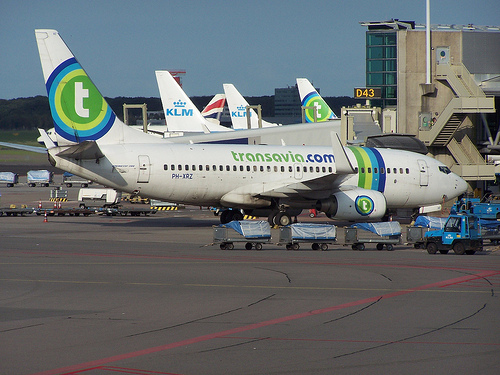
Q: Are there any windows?
A: Yes, there is a window.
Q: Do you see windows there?
A: Yes, there is a window.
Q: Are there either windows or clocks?
A: Yes, there is a window.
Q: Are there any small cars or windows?
A: Yes, there is a small window.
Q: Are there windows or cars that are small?
A: Yes, the window is small.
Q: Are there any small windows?
A: Yes, there is a small window.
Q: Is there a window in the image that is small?
A: Yes, there is a window that is small.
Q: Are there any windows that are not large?
A: Yes, there is a small window.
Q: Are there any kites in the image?
A: No, there are no kites.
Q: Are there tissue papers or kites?
A: No, there are no kites or tissue papers.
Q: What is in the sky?
A: The clouds are in the sky.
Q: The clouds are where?
A: The clouds are in the sky.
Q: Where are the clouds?
A: The clouds are in the sky.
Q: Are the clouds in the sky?
A: Yes, the clouds are in the sky.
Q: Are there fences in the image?
A: No, there are no fences.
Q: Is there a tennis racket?
A: No, there are no rackets.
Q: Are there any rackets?
A: No, there are no rackets.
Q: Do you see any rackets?
A: No, there are no rackets.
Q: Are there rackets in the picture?
A: No, there are no rackets.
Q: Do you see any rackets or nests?
A: No, there are no rackets or nests.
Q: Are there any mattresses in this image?
A: No, there are no mattresses.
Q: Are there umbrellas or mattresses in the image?
A: No, there are no mattresses or umbrellas.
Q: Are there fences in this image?
A: No, there are no fences.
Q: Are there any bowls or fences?
A: No, there are no fences or bowls.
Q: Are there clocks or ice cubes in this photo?
A: No, there are no clocks or ice cubes.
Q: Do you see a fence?
A: No, there are no fences.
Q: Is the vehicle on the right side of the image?
A: Yes, the vehicle is on the right of the image.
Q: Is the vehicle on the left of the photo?
A: No, the vehicle is on the right of the image.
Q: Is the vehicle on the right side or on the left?
A: The vehicle is on the right of the image.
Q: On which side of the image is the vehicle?
A: The vehicle is on the right of the image.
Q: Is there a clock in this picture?
A: No, there are no clocks.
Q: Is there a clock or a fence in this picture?
A: No, there are no clocks or fences.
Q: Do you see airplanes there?
A: Yes, there is an airplane.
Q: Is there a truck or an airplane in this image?
A: Yes, there is an airplane.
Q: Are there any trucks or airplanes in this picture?
A: Yes, there is an airplane.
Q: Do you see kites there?
A: No, there are no kites.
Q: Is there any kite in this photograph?
A: No, there are no kites.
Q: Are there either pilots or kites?
A: No, there are no kites or pilots.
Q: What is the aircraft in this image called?
A: The aircraft is an airplane.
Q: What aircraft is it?
A: The aircraft is an airplane.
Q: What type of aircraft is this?
A: This is an airplane.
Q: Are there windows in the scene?
A: Yes, there is a window.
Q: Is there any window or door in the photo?
A: Yes, there is a window.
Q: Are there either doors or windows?
A: Yes, there is a window.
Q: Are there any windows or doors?
A: Yes, there is a window.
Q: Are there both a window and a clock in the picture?
A: No, there is a window but no clocks.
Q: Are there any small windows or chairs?
A: Yes, there is a small window.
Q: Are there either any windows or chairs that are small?
A: Yes, the window is small.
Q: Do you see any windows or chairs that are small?
A: Yes, the window is small.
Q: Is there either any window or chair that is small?
A: Yes, the window is small.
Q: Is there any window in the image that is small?
A: Yes, there is a window that is small.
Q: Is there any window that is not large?
A: Yes, there is a small window.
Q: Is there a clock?
A: No, there are no clocks.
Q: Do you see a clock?
A: No, there are no clocks.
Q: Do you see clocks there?
A: No, there are no clocks.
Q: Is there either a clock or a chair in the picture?
A: No, there are no clocks or chairs.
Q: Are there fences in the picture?
A: No, there are no fences.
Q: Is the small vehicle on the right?
A: Yes, the vehicle is on the right of the image.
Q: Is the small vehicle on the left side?
A: No, the vehicle is on the right of the image.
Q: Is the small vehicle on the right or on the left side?
A: The vehicle is on the right of the image.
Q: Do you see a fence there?
A: No, there are no fences.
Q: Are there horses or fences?
A: No, there are no fences or horses.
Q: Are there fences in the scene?
A: No, there are no fences.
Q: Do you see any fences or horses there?
A: No, there are no fences or horses.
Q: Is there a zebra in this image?
A: No, there are no zebras.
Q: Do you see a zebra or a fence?
A: No, there are no zebras or fences.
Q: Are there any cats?
A: No, there are no cats.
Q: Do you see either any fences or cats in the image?
A: No, there are no cats or fences.